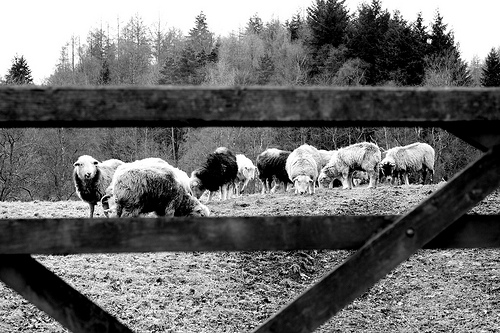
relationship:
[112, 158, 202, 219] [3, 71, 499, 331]
sheep through fence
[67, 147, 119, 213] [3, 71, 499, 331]
sheep through fence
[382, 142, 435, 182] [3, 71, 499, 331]
sheep through fence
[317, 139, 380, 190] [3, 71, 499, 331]
sheep through fence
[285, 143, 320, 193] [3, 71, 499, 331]
sheep through fence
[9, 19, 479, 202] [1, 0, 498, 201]
hill with trees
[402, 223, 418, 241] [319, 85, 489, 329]
bolt on gate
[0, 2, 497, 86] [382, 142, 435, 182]
sky over sheep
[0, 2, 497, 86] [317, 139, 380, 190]
sky over sheep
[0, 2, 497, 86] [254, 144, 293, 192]
sky over black sheep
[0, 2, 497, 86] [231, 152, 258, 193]
sky over sheep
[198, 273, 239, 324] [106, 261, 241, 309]
grass on ground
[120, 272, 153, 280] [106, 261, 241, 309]
dirt on ground